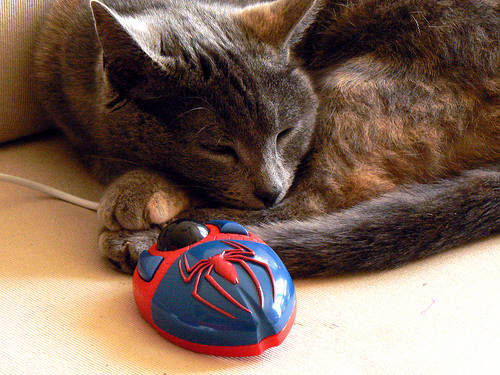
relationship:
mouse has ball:
[125, 220, 296, 354] [154, 218, 211, 249]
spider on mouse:
[177, 246, 282, 320] [125, 220, 296, 354]